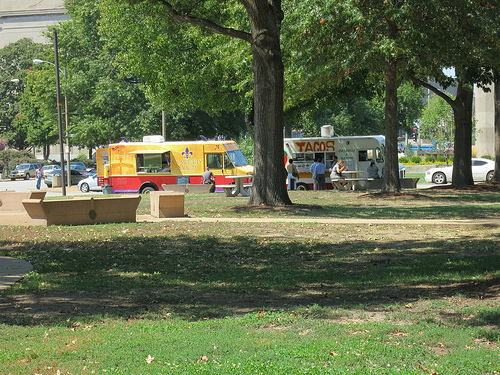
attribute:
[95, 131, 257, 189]
truck — yellow food , red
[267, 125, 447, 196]
truck — white taco food 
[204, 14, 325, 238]
tree trunk — wide, bare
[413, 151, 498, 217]
car — white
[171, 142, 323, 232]
table — empty, picnic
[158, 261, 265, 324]
grass — green, lush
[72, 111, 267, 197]
truck — yellow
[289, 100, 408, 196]
truck — taco, white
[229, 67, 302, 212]
tree — tall, thick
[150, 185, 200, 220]
bench — brown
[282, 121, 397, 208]
truck — white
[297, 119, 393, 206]
truck — white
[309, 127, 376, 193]
truck — white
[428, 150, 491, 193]
car — white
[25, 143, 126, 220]
lot — parking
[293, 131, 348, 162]
letters — red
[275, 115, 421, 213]
truck — white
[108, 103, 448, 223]
trucks — food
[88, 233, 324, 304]
shadow — large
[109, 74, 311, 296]
tree — big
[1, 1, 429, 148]
trees — green, leafy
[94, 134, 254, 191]
truck — yellow, red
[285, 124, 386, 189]
truck — white, taco vendor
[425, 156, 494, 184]
car — white, parked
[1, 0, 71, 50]
building — gray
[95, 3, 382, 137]
tree — green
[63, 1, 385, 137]
tree — green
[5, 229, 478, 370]
grass — green, lush